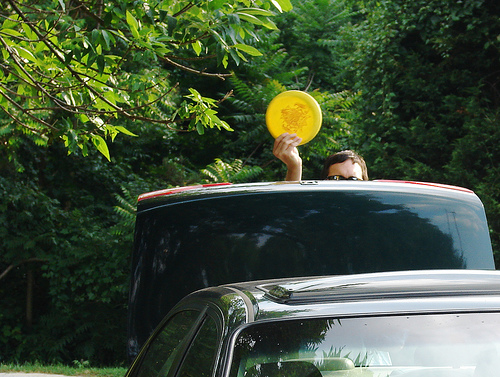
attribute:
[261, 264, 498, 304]
sunroof — black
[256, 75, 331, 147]
frisbee — plastic, yellow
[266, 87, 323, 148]
frisbee — yellow 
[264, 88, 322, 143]
frisbee — yellow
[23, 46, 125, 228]
leaves — green 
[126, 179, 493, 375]
car — black 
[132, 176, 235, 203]
tail light — red 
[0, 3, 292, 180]
green tree — lush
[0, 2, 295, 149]
leaves — green 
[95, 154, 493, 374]
car — black 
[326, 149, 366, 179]
hair — short, brown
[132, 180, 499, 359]
trunk — raised, black